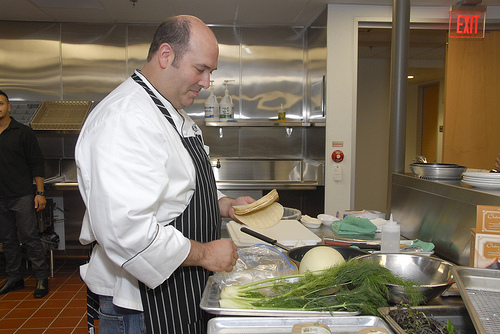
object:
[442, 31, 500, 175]
door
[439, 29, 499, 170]
wood color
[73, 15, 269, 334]
man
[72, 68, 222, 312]
shirt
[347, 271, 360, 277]
green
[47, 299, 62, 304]
red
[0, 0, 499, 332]
kitchen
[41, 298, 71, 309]
tile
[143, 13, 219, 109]
head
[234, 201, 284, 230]
shells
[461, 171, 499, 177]
plates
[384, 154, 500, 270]
shelf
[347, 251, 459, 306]
bowl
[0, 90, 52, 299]
man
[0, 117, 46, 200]
shirt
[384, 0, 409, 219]
pole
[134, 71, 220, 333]
apron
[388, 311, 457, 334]
vegetables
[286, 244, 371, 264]
pan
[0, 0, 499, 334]
background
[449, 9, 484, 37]
sign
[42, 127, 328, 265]
sink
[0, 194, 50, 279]
pants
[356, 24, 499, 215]
doorwa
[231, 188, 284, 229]
bread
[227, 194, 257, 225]
hand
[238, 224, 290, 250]
knife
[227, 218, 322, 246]
board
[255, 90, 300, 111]
chemicals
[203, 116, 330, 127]
counter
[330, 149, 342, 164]
alarm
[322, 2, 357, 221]
wall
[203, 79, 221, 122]
bottles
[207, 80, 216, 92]
pump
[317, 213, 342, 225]
dishes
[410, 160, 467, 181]
plates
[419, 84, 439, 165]
door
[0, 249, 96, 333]
floor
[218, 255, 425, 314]
herbs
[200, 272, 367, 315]
tray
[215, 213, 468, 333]
counter